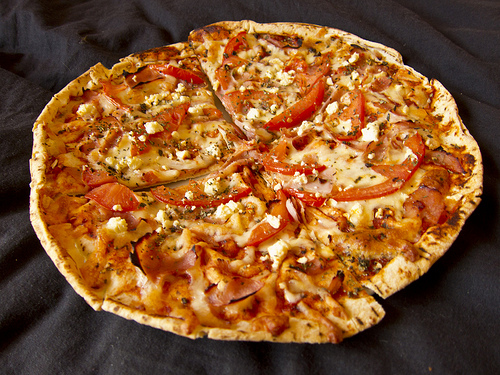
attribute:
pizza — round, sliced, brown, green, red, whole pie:
[16, 14, 493, 352]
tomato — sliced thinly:
[163, 60, 208, 93]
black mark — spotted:
[132, 238, 140, 271]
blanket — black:
[38, 3, 164, 17]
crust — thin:
[364, 262, 423, 287]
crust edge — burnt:
[139, 21, 231, 65]